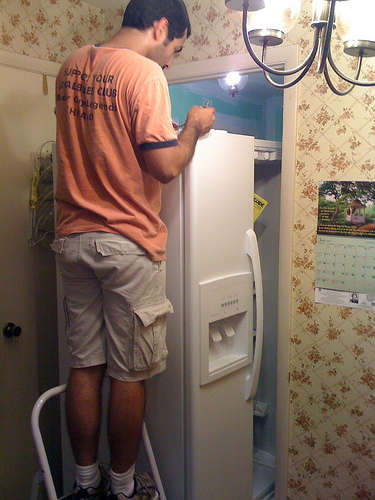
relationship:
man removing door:
[52, 1, 214, 498] [182, 131, 263, 499]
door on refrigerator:
[182, 131, 263, 499] [51, 128, 264, 500]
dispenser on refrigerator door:
[195, 266, 260, 387] [169, 118, 271, 498]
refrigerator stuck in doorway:
[29, 128, 281, 496] [167, 57, 309, 322]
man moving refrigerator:
[52, 1, 214, 498] [29, 128, 281, 496]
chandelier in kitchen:
[228, 6, 369, 87] [1, 0, 373, 498]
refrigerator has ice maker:
[51, 128, 264, 500] [203, 308, 252, 373]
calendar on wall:
[312, 173, 373, 308] [300, 120, 373, 381]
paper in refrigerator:
[255, 191, 267, 221] [47, 124, 251, 499]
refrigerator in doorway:
[51, 128, 264, 500] [157, 42, 302, 498]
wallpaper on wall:
[3, 2, 374, 497] [4, 0, 374, 495]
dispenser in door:
[208, 308, 247, 366] [164, 124, 270, 499]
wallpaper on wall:
[0, 0, 375, 500] [248, 3, 371, 485]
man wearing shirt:
[52, 1, 214, 498] [18, 26, 206, 268]